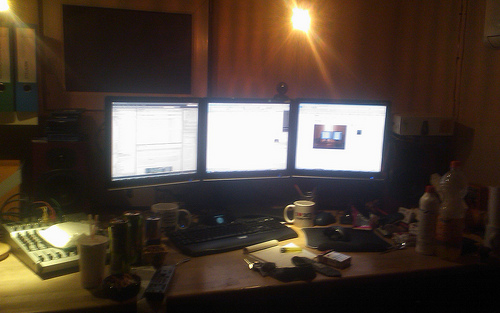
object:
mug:
[283, 200, 319, 230]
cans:
[105, 211, 149, 272]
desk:
[2, 197, 499, 312]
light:
[279, 2, 323, 43]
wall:
[206, 3, 498, 114]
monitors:
[109, 95, 393, 186]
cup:
[77, 232, 106, 290]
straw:
[87, 214, 102, 239]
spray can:
[415, 183, 442, 254]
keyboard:
[165, 215, 297, 256]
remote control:
[146, 261, 174, 301]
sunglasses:
[399, 240, 417, 253]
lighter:
[279, 244, 306, 254]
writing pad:
[240, 236, 317, 272]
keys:
[242, 255, 270, 282]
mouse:
[325, 224, 354, 239]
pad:
[296, 223, 396, 253]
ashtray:
[99, 270, 142, 298]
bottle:
[439, 158, 469, 261]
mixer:
[80, 233, 106, 289]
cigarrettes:
[314, 247, 352, 266]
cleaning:
[416, 181, 440, 254]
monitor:
[104, 97, 202, 185]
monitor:
[206, 100, 292, 176]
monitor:
[294, 98, 391, 177]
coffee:
[78, 238, 110, 291]